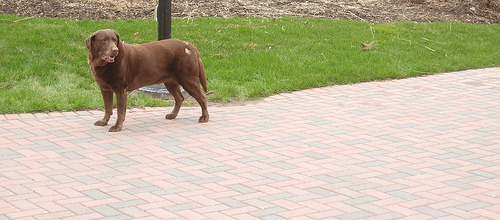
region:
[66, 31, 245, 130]
the dog is brown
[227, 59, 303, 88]
the grass is green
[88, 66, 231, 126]
the dog has four legs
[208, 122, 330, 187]
the floor is bricked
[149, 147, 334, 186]
the tiles are red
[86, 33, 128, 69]
the dog's nose is brown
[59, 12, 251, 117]
the dog is standing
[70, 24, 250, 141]
one dog standing on the floor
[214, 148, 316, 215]
the tiles are rectangle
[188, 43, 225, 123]
the dog has tail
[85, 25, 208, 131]
Dog standing on brick pavement.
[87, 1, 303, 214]
Red dog standing before a black pole.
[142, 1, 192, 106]
Bottom of a black pole.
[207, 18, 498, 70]
Green and brown grass on the ground.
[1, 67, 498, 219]
Brick side walk on the ground.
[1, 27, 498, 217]
Dog standing on a brick sidewalk.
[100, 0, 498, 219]
Black and silver pole beside a brick sidewalk.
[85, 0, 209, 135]
Gray and black pole behind the dog.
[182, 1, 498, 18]
Dry grass behind the green grass.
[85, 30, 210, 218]
Dog with head turned looking with mouth open.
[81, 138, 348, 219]
pavement is red and black color.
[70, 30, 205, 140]
One dog is seen.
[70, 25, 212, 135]
Dog is brown color.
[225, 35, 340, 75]
Grass is green color.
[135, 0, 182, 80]
Pole is grey color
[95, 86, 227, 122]
Four legs for dog.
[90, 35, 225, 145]
Dog is standing in the pavement.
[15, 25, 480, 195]
day time picture.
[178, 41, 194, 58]
Two white spots in dog.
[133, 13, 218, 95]
pole is in grass.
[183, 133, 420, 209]
pavement is red and black color.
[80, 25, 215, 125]
dog is brown color.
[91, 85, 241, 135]
Dog has four legs.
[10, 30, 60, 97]
Grass is green color.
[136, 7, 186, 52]
Pole is grey color.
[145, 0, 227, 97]
Pole is in grass.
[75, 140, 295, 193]
Pavement is made of bricks.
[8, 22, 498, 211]
Day time picture.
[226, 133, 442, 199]
stone brick path way to house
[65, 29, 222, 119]
large brown golden retriever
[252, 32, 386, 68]
freshly cut green grass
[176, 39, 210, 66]
white spot on dogs fur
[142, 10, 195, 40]
black metal street pole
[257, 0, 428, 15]
dried dead hay and grass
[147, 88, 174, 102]
silver bottom of pole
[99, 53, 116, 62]
dogs opened pink mouth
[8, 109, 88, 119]
border of pathway made from stones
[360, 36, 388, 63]
small bunch of leaves